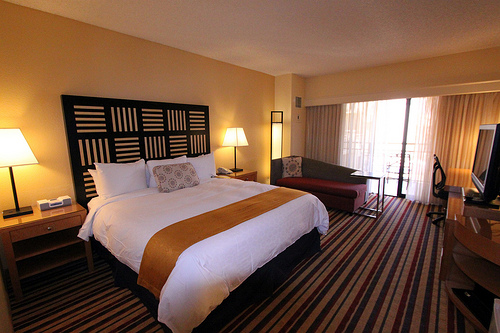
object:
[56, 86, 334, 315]
suite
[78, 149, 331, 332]
bed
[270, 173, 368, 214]
chair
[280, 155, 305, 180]
pillow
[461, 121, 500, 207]
television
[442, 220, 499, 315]
stand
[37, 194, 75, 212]
box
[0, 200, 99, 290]
table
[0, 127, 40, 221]
lamps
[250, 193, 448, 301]
carpeting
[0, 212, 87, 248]
drawer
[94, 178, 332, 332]
bedspread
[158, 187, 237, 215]
line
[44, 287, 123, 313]
stripes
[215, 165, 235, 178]
clock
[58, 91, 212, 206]
headboard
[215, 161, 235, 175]
phone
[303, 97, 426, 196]
blinds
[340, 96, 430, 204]
window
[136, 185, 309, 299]
blanket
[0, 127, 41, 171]
light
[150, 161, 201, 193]
case